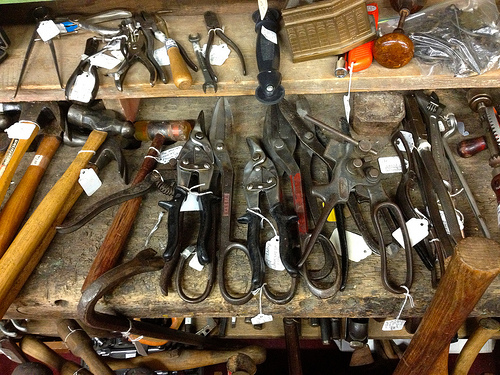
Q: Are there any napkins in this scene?
A: No, there are no napkins.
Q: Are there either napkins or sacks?
A: No, there are no napkins or sacks.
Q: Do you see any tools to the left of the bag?
A: Yes, there are tools to the left of the bag.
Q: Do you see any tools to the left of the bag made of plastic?
A: Yes, there are tools to the left of the bag.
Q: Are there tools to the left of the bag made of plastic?
A: Yes, there are tools to the left of the bag.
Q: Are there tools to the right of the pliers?
A: Yes, there are tools to the right of the pliers.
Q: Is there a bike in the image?
A: No, there are no bikes.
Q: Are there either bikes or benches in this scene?
A: No, there are no bikes or benches.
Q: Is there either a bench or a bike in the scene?
A: No, there are no bikes or benches.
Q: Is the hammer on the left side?
A: Yes, the hammer is on the left of the image.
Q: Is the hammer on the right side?
A: No, the hammer is on the left of the image.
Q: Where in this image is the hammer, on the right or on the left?
A: The hammer is on the left of the image.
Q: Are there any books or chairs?
A: No, there are no chairs or books.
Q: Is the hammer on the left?
A: Yes, the hammer is on the left of the image.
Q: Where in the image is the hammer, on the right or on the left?
A: The hammer is on the left of the image.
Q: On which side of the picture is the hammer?
A: The hammer is on the left of the image.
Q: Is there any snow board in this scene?
A: No, there are no snowboards.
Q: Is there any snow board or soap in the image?
A: No, there are no snowboards or soaps.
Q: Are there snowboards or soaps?
A: No, there are no snowboards or soaps.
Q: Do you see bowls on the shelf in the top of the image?
A: No, there is a tool on the shelf.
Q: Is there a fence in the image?
A: No, there are no fences.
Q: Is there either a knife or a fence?
A: No, there are no fences or knives.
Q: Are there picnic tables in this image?
A: No, there are no picnic tables.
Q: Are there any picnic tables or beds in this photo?
A: No, there are no picnic tables or beds.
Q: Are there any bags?
A: Yes, there is a bag.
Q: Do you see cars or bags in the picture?
A: Yes, there is a bag.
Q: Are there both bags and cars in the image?
A: No, there is a bag but no cars.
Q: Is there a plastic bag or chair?
A: Yes, there is a plastic bag.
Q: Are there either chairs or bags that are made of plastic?
A: Yes, the bag is made of plastic.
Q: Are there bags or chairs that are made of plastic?
A: Yes, the bag is made of plastic.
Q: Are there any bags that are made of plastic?
A: Yes, there is a bag that is made of plastic.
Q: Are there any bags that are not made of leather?
A: Yes, there is a bag that is made of plastic.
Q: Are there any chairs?
A: No, there are no chairs.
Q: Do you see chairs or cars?
A: No, there are no chairs or cars.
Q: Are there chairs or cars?
A: No, there are no chairs or cars.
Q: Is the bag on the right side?
A: Yes, the bag is on the right of the image.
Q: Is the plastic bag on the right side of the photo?
A: Yes, the bag is on the right of the image.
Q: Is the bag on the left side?
A: No, the bag is on the right of the image.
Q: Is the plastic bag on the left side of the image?
A: No, the bag is on the right of the image.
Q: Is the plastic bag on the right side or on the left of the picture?
A: The bag is on the right of the image.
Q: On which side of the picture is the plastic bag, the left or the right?
A: The bag is on the right of the image.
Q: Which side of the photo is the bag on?
A: The bag is on the right of the image.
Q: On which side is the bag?
A: The bag is on the right of the image.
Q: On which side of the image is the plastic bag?
A: The bag is on the right of the image.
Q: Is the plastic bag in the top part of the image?
A: Yes, the bag is in the top of the image.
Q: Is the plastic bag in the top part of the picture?
A: Yes, the bag is in the top of the image.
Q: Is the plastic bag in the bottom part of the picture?
A: No, the bag is in the top of the image.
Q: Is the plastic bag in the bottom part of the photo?
A: No, the bag is in the top of the image.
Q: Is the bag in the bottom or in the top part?
A: The bag is in the top of the image.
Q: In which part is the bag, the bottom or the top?
A: The bag is in the top of the image.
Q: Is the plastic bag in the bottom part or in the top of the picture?
A: The bag is in the top of the image.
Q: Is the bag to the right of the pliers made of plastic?
A: Yes, the bag is made of plastic.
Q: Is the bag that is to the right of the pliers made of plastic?
A: Yes, the bag is made of plastic.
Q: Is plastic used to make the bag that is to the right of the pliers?
A: Yes, the bag is made of plastic.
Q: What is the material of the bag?
A: The bag is made of plastic.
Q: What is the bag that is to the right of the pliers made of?
A: The bag is made of plastic.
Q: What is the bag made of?
A: The bag is made of plastic.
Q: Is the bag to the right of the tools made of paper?
A: No, the bag is made of plastic.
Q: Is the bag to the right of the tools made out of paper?
A: No, the bag is made of plastic.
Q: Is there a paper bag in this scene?
A: No, there is a bag but it is made of plastic.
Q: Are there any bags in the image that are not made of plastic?
A: No, there is a bag but it is made of plastic.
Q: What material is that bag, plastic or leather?
A: The bag is made of plastic.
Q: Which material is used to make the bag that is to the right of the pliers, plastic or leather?
A: The bag is made of plastic.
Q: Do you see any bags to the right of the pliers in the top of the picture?
A: Yes, there is a bag to the right of the pliers.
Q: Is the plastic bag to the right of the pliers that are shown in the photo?
A: Yes, the bag is to the right of the pliers.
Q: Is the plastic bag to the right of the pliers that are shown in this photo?
A: Yes, the bag is to the right of the pliers.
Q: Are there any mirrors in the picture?
A: No, there are no mirrors.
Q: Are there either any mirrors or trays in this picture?
A: No, there are no mirrors or trays.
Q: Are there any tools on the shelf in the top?
A: Yes, there is a tool on the shelf.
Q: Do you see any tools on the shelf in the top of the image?
A: Yes, there is a tool on the shelf.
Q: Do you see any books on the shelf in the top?
A: No, there is a tool on the shelf.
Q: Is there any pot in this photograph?
A: No, there are no pots.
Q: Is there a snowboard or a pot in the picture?
A: No, there are no pots or snowboards.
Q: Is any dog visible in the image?
A: No, there are no dogs.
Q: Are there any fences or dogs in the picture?
A: No, there are no dogs or fences.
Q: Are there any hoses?
A: No, there are no hoses.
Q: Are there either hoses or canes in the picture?
A: No, there are no hoses or canes.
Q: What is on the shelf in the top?
A: The tool is on the shelf.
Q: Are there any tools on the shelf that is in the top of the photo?
A: Yes, there is a tool on the shelf.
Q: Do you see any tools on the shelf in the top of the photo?
A: Yes, there is a tool on the shelf.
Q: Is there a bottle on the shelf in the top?
A: No, there is a tool on the shelf.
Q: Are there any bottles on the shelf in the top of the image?
A: No, there is a tool on the shelf.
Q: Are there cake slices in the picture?
A: No, there are no cake slices.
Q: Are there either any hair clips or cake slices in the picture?
A: No, there are no cake slices or hair clips.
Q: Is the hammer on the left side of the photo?
A: Yes, the hammer is on the left of the image.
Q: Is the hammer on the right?
A: No, the hammer is on the left of the image.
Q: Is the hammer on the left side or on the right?
A: The hammer is on the left of the image.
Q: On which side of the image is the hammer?
A: The hammer is on the left of the image.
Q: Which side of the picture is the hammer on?
A: The hammer is on the left of the image.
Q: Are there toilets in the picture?
A: No, there are no toilets.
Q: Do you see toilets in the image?
A: No, there are no toilets.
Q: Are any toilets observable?
A: No, there are no toilets.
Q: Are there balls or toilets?
A: No, there are no toilets or balls.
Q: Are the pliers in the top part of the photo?
A: Yes, the pliers are in the top of the image.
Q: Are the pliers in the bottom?
A: No, the pliers are in the top of the image.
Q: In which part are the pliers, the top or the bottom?
A: The pliers are in the top of the image.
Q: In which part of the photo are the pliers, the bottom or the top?
A: The pliers are in the top of the image.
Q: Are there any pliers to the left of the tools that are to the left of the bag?
A: Yes, there are pliers to the left of the tools.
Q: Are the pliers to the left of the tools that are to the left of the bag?
A: Yes, the pliers are to the left of the tools.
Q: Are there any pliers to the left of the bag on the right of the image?
A: Yes, there are pliers to the left of the bag.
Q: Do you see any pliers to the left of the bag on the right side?
A: Yes, there are pliers to the left of the bag.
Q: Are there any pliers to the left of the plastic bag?
A: Yes, there are pliers to the left of the bag.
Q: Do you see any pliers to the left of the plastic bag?
A: Yes, there are pliers to the left of the bag.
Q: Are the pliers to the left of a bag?
A: Yes, the pliers are to the left of a bag.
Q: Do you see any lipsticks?
A: No, there are no lipsticks.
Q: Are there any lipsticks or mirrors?
A: No, there are no lipsticks or mirrors.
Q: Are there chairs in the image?
A: No, there are no chairs.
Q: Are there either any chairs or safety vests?
A: No, there are no chairs or safety vests.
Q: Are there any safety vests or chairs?
A: No, there are no chairs or safety vests.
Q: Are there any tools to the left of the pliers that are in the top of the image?
A: Yes, there is a tool to the left of the pliers.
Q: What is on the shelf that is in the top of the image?
A: The tool is on the shelf.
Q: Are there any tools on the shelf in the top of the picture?
A: Yes, there is a tool on the shelf.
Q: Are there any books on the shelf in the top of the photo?
A: No, there is a tool on the shelf.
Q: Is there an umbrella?
A: No, there are no umbrellas.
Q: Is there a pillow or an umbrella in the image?
A: No, there are no umbrellas or pillows.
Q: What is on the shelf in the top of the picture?
A: The tool is on the shelf.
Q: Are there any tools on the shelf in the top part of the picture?
A: Yes, there is a tool on the shelf.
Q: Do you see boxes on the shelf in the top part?
A: No, there is a tool on the shelf.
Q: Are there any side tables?
A: No, there are no side tables.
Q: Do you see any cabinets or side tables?
A: No, there are no side tables or cabinets.